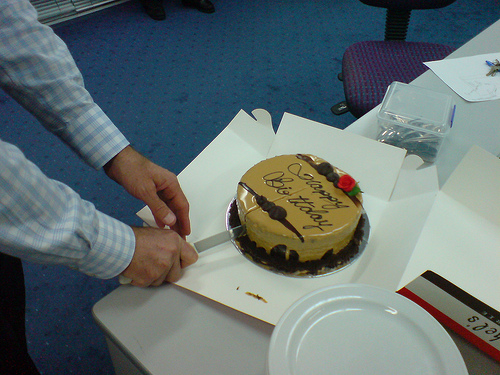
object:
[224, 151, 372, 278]
cake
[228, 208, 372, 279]
white dish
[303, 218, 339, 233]
black letter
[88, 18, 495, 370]
desk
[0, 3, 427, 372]
carpet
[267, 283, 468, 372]
plate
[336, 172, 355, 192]
rose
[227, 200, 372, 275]
base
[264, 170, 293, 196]
letter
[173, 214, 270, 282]
knife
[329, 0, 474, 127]
chair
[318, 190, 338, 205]
letter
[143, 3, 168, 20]
shoe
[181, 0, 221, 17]
shoe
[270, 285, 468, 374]
dish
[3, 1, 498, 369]
floor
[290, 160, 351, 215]
happy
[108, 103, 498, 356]
box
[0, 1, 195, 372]
person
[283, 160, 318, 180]
letter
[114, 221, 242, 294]
hand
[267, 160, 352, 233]
lettering